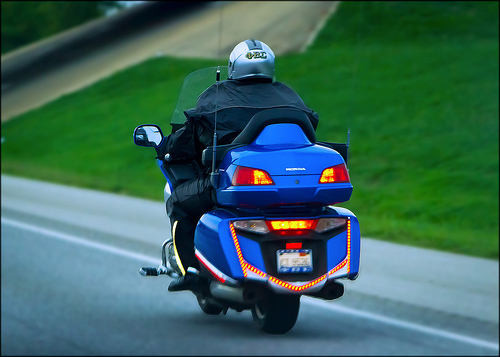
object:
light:
[264, 219, 318, 236]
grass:
[0, 0, 499, 260]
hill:
[0, 0, 498, 324]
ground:
[0, 176, 499, 357]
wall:
[394, 127, 498, 177]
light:
[231, 165, 275, 185]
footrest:
[139, 265, 168, 276]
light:
[318, 163, 350, 183]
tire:
[251, 286, 300, 334]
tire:
[196, 296, 225, 315]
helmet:
[227, 39, 275, 82]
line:
[0, 216, 499, 350]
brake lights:
[232, 165, 275, 186]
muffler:
[209, 281, 259, 304]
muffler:
[305, 280, 344, 300]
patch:
[0, 73, 139, 191]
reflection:
[142, 122, 159, 142]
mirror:
[133, 124, 164, 148]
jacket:
[155, 78, 348, 165]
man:
[165, 39, 317, 291]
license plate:
[276, 249, 313, 273]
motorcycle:
[132, 66, 361, 335]